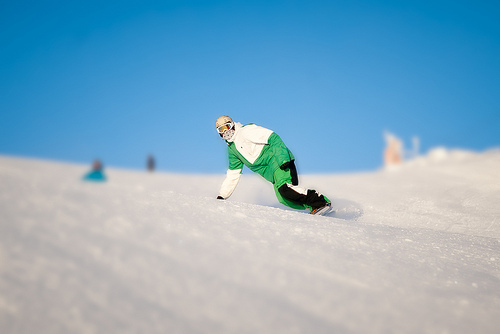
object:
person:
[216, 114, 332, 216]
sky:
[1, 0, 499, 176]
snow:
[0, 147, 499, 333]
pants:
[270, 164, 329, 213]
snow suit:
[218, 121, 331, 211]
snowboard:
[307, 200, 331, 216]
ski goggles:
[216, 122, 235, 135]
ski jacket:
[220, 121, 296, 199]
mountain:
[0, 145, 499, 331]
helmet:
[216, 116, 233, 131]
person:
[80, 158, 107, 182]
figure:
[146, 153, 157, 170]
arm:
[216, 147, 243, 200]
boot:
[312, 197, 328, 216]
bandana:
[221, 130, 234, 141]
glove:
[280, 163, 291, 171]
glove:
[216, 195, 224, 200]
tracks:
[5, 210, 346, 333]